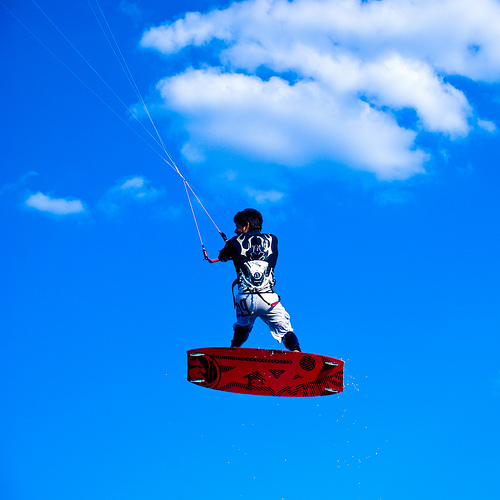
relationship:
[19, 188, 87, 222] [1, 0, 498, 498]
cloud in sky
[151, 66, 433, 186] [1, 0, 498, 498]
cloud in sky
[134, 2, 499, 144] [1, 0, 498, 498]
cloud in sky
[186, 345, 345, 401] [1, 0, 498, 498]
windboard in photo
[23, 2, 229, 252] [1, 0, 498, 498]
string in sky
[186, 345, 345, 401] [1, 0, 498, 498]
windboard in sky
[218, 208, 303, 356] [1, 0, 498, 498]
man windsurfing in sky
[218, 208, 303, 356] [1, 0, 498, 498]
man in sky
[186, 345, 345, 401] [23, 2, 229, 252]
windboard under string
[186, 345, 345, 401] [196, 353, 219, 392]
windboard has design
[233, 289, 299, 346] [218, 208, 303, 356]
pants on man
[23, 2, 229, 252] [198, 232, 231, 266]
string attached to rod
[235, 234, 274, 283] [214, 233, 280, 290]
design on shirt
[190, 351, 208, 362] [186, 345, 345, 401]
fin underneath windboard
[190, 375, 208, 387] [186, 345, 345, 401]
fin underneath windboard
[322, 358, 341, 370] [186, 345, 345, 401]
fin underneath windboard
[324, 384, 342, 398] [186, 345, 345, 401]
fin underneath windboard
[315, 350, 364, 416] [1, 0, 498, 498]
water in sky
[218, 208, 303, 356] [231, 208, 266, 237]
man has head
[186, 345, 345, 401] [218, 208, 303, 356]
windboard under man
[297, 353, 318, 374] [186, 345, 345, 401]
circle on windboard.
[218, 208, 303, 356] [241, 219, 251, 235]
man has ear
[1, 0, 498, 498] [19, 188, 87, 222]
sky has cloud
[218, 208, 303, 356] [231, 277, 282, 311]
man wearing suspender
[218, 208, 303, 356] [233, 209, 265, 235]
man has hair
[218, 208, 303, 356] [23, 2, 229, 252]
man holding string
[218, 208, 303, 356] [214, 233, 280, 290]
man wearing shirt